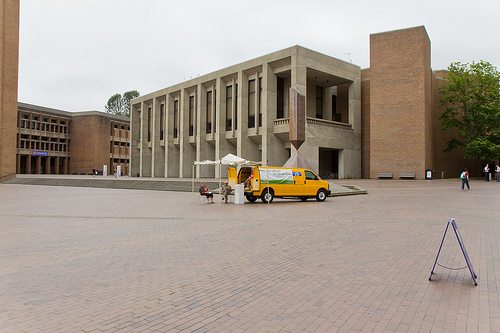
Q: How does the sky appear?
A: Overcast.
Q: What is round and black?
A: Tires.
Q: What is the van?
A: Yellow.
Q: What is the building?
A: Gray.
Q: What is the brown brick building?
A: Large.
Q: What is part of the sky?
A: White.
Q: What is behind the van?
A: The building.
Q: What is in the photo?
A: Buildings.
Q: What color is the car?
A: Yellow.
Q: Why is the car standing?
A: It is parked.